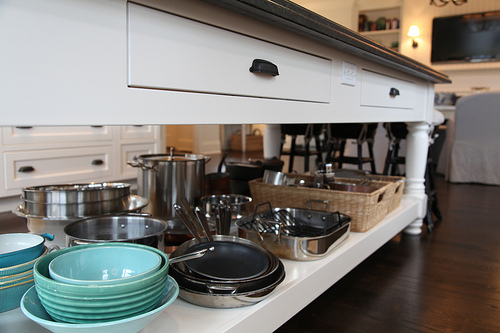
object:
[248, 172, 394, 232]
basket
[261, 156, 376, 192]
items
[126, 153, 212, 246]
cookware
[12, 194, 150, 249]
cookware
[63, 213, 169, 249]
cookware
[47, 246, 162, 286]
cookware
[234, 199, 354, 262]
cookware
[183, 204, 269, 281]
pans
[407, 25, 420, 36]
shade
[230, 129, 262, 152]
basket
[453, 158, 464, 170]
ground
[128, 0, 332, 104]
drawer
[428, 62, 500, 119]
shelf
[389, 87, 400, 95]
handle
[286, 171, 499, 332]
floor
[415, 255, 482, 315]
wood flooring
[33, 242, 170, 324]
bowls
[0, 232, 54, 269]
bowls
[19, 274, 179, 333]
bowl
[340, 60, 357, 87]
outlet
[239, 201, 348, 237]
rack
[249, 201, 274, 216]
handle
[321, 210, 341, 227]
handle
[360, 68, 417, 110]
drawer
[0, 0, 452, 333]
shelf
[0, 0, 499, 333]
room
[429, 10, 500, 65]
tv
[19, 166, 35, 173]
black handles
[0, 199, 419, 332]
white shelf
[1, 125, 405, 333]
kitchen items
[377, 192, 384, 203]
holes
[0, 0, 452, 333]
counter top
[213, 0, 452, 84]
edge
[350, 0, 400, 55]
shelf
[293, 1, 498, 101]
wall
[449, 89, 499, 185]
chair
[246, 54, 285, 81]
handle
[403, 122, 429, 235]
leg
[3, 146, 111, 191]
drawer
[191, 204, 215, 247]
handle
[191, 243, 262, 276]
coating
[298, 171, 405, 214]
basket